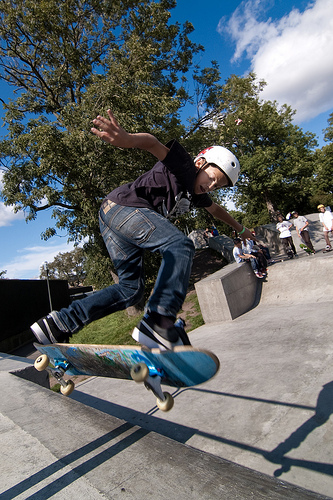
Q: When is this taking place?
A: Daytime.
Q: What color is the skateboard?
A: Blue.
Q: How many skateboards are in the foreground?
A: One.